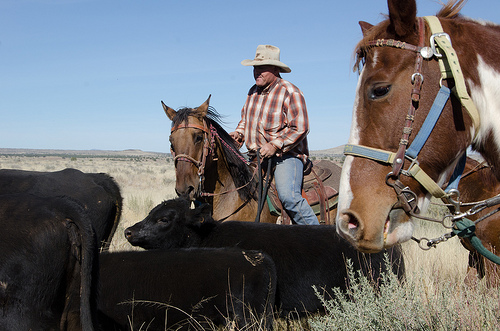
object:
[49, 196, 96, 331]
tail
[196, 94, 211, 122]
ear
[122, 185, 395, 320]
cows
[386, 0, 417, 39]
ear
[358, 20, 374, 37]
ear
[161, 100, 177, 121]
ear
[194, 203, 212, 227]
ear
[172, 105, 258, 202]
mane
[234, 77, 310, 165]
shirt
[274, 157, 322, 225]
jeans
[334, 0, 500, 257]
horse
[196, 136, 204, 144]
eye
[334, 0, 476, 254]
head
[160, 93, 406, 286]
horse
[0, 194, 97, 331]
cattle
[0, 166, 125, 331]
cattle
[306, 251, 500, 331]
weeds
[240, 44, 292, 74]
hat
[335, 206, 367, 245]
nose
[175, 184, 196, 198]
nose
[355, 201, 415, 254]
mouth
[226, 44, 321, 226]
cowboy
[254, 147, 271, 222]
reins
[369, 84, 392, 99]
eye